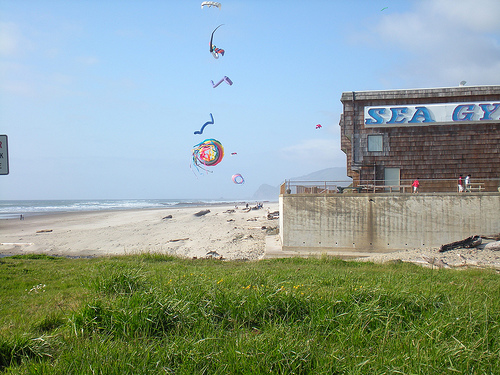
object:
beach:
[0, 199, 280, 262]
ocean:
[0, 196, 272, 219]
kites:
[192, 111, 217, 135]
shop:
[277, 84, 500, 254]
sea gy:
[364, 101, 500, 125]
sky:
[0, 0, 500, 196]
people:
[411, 179, 420, 194]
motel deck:
[281, 175, 500, 196]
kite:
[190, 138, 225, 174]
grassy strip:
[0, 252, 500, 375]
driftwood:
[193, 209, 211, 218]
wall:
[280, 191, 500, 254]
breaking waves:
[10, 206, 43, 211]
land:
[0, 204, 500, 375]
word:
[364, 106, 437, 126]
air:
[6, 0, 329, 187]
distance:
[0, 180, 279, 208]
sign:
[363, 99, 500, 129]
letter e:
[406, 105, 438, 124]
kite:
[210, 75, 234, 88]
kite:
[200, 0, 225, 10]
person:
[457, 174, 464, 194]